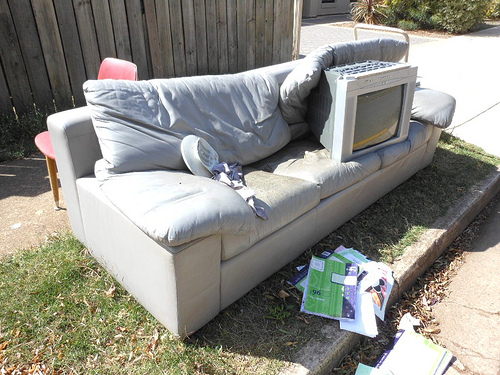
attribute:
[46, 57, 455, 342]
couch — white, gray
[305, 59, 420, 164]
television — old, silver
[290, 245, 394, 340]
papers — green, white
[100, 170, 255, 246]
cushion — dirty, large, smushed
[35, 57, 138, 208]
chair — red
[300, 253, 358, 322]
paper — green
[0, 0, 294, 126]
fence — wood, gray